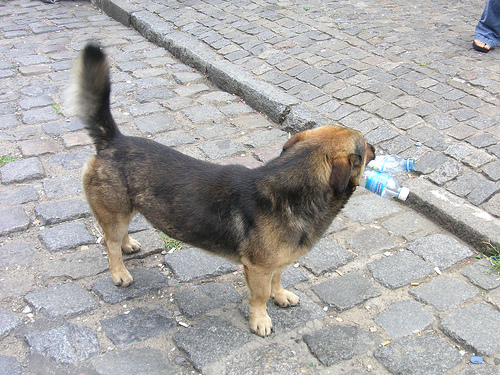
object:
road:
[1, 0, 500, 120]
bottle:
[359, 167, 411, 202]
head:
[284, 124, 376, 200]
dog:
[78, 42, 377, 338]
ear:
[334, 151, 353, 195]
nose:
[367, 143, 377, 163]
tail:
[77, 41, 125, 151]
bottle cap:
[397, 186, 412, 201]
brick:
[311, 269, 381, 313]